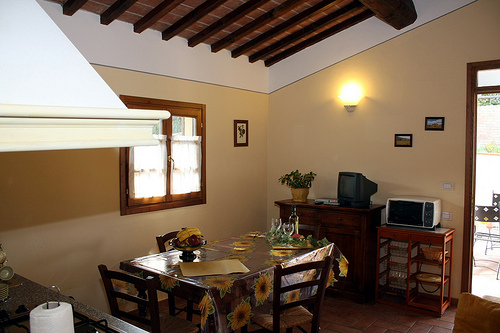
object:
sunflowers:
[196, 275, 272, 329]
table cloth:
[114, 229, 344, 331]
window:
[113, 95, 205, 217]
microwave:
[383, 196, 441, 228]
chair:
[247, 254, 335, 333]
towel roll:
[24, 281, 73, 332]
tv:
[332, 167, 379, 210]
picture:
[422, 115, 445, 131]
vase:
[290, 187, 310, 203]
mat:
[175, 256, 248, 278]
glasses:
[265, 213, 297, 251]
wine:
[285, 199, 299, 243]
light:
[335, 78, 362, 113]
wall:
[269, 58, 459, 167]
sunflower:
[203, 272, 237, 296]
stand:
[370, 224, 451, 316]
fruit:
[168, 225, 207, 254]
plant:
[276, 168, 312, 188]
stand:
[275, 202, 378, 246]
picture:
[391, 132, 410, 149]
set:
[393, 116, 443, 148]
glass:
[279, 222, 291, 248]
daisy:
[223, 296, 256, 330]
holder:
[44, 282, 60, 308]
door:
[458, 56, 500, 295]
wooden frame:
[461, 59, 476, 292]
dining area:
[84, 196, 362, 327]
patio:
[471, 94, 500, 294]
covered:
[126, 135, 209, 202]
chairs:
[470, 192, 500, 279]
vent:
[0, 1, 169, 156]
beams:
[57, 2, 418, 63]